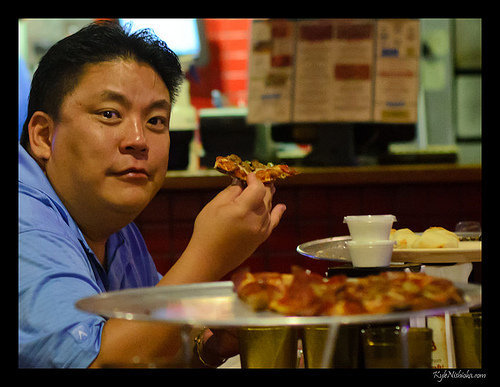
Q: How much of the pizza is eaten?
A: Half.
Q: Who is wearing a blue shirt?
A: The man.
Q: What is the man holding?
A: Pizza.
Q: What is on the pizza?
A: Pepperoni.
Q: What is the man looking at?
A: The camera.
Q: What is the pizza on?
A: A pan.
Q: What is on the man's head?
A: Hair.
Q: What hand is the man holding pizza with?
A: Right.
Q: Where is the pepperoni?
A: On the pizza.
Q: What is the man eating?
A: Pizza.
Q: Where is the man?
A: At a pizza restaurant.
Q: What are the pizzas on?
A: Silver pan.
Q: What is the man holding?
A: Piece of pizza.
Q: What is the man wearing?
A: Blue shirt.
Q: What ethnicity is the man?
A: Asian.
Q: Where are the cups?
A: Center of the table, under the pizza trays.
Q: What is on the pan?
A: Pizza.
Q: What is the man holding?
A: Pizza,.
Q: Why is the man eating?
A: Hunger.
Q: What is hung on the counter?
A: A menu.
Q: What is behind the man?
A: A counter.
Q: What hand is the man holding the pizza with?
A: Right.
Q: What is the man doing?
A: Eating pizza.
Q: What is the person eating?
A: Pizza.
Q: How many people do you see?
A: One.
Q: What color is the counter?
A: Brown.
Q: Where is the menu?
A: On the counter.